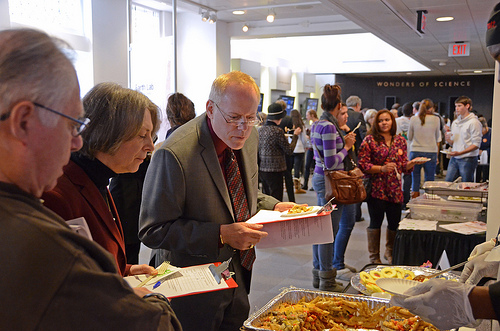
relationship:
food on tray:
[251, 296, 436, 331] [237, 280, 390, 329]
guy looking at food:
[138, 70, 308, 331] [251, 296, 436, 331]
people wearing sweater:
[310, 83, 356, 292] [307, 112, 346, 185]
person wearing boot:
[356, 109, 430, 265] [364, 222, 386, 271]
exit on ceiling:
[443, 38, 474, 66] [320, 1, 498, 73]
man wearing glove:
[389, 4, 499, 329] [391, 263, 482, 329]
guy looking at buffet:
[138, 70, 308, 331] [240, 262, 465, 329]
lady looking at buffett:
[42, 81, 163, 276] [169, 181, 480, 316]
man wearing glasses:
[1, 26, 183, 329] [8, 99, 91, 133]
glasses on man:
[35, 90, 92, 122] [15, 56, 89, 327]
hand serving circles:
[398, 280, 496, 325] [359, 267, 415, 291]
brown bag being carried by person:
[327, 164, 368, 201] [356, 109, 430, 265]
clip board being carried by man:
[244, 196, 336, 226] [138, 70, 306, 327]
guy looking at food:
[133, 76, 298, 326] [251, 278, 441, 328]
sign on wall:
[369, 77, 475, 92] [336, 72, 484, 159]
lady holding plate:
[79, 82, 149, 275] [401, 154, 431, 165]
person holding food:
[356, 109, 430, 265] [411, 153, 433, 165]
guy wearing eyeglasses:
[138, 70, 308, 331] [221, 112, 261, 130]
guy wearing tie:
[138, 70, 308, 331] [216, 148, 244, 219]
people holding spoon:
[310, 83, 356, 292] [347, 116, 372, 160]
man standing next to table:
[1, 28, 182, 331] [317, 262, 499, 330]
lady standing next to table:
[42, 81, 163, 276] [317, 262, 499, 330]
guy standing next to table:
[138, 70, 308, 331] [317, 262, 499, 330]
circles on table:
[359, 267, 415, 291] [317, 262, 499, 330]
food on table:
[237, 280, 449, 329] [317, 262, 499, 330]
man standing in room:
[1, 28, 182, 331] [5, 2, 498, 330]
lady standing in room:
[42, 81, 163, 276] [5, 2, 498, 330]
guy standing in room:
[138, 70, 308, 331] [5, 2, 498, 330]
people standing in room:
[310, 83, 356, 292] [5, 2, 498, 330]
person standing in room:
[359, 109, 410, 265] [5, 2, 498, 330]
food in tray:
[251, 296, 436, 331] [245, 285, 435, 330]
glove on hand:
[397, 273, 478, 330] [390, 280, 477, 330]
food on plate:
[288, 204, 304, 213] [282, 210, 320, 217]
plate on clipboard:
[282, 210, 320, 217] [244, 199, 336, 221]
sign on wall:
[376, 81, 471, 88] [334, 71, 493, 119]